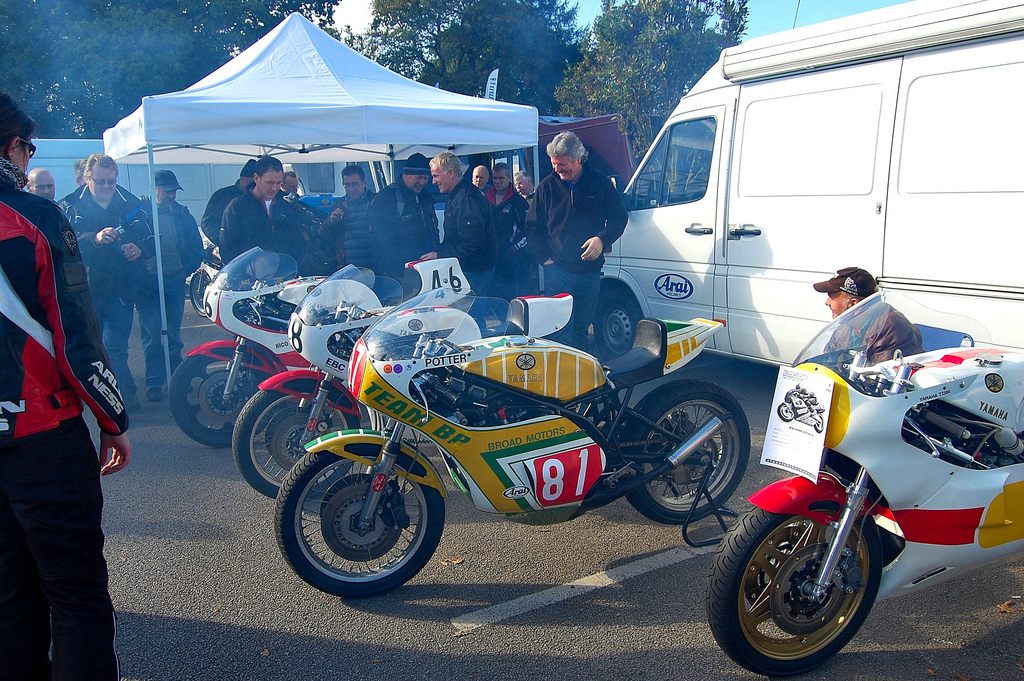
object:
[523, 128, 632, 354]
man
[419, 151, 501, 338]
man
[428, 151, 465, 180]
hair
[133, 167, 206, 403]
men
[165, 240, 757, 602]
three motorcycles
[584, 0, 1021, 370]
van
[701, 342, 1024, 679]
motorcycle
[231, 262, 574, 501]
motorcycle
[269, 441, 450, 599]
front wheel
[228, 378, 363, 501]
front wheel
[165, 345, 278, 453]
front wheel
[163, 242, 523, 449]
bike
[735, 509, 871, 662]
rim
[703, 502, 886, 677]
wheel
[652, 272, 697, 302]
oval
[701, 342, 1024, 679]
motorcycles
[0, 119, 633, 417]
people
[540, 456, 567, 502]
number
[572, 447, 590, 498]
number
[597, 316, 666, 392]
seat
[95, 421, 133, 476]
person's hand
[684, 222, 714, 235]
handle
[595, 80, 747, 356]
door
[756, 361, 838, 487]
paper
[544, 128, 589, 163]
hair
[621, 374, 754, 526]
back wheel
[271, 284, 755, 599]
bike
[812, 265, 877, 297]
baseball cap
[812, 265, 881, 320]
head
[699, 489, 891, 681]
front wheel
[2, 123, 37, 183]
person's face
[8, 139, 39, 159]
glasses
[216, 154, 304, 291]
person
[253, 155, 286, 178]
hair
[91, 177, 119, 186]
sunglasses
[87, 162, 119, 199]
man's face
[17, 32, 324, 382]
smoke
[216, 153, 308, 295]
men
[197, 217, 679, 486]
bikes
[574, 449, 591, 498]
numbers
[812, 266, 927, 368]
man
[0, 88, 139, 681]
guy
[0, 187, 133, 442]
jacket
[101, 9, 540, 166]
canopy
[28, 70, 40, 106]
trees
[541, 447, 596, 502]
number 81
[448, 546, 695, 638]
stripe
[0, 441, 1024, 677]
ground